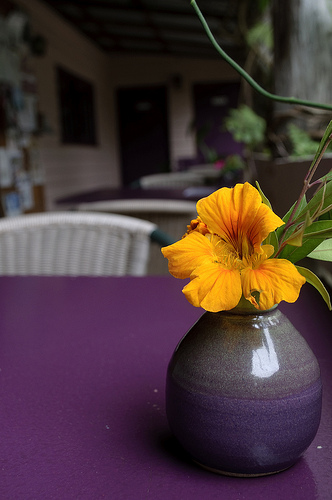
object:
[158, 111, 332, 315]
plant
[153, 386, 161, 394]
crumb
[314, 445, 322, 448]
crumb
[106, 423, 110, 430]
crumb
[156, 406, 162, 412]
crumb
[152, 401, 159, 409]
crumb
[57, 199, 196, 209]
tablecloth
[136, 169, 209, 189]
chair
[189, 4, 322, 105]
wire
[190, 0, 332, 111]
cable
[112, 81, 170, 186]
door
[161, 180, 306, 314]
flower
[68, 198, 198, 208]
table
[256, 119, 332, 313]
leaves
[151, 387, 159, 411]
crumbs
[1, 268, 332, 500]
tablecloth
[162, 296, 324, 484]
vase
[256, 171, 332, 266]
leaf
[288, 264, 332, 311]
leaf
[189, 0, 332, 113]
green cable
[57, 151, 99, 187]
blank wall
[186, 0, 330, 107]
stem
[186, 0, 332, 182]
plants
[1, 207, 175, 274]
chair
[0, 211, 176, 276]
seat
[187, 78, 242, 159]
door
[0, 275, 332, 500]
table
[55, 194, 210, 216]
tablecloth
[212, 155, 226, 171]
flower